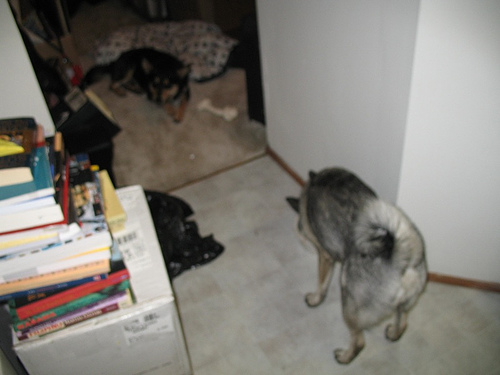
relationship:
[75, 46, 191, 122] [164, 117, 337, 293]
animal laying on floor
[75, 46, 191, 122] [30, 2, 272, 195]
animal on carpet floor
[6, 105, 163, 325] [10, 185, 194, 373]
books on box